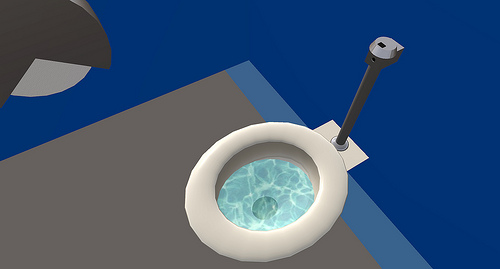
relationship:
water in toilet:
[217, 157, 315, 231] [184, 118, 370, 262]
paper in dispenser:
[10, 59, 92, 99] [0, 0, 112, 109]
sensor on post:
[369, 56, 378, 63] [338, 36, 405, 146]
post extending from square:
[338, 36, 405, 146] [315, 119, 369, 171]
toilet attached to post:
[184, 118, 370, 262] [338, 36, 405, 146]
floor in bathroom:
[0, 70, 385, 268] [1, 0, 500, 268]